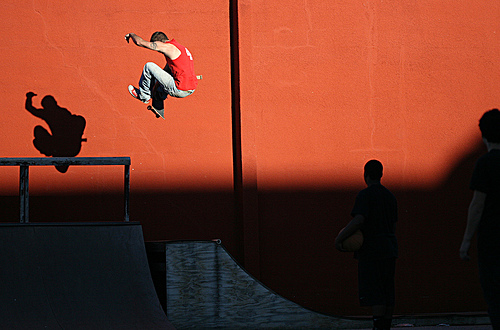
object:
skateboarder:
[126, 31, 201, 120]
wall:
[1, 8, 484, 184]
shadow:
[24, 92, 84, 174]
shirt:
[159, 40, 197, 91]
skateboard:
[149, 82, 166, 120]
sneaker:
[127, 84, 148, 102]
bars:
[0, 153, 131, 168]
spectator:
[335, 158, 401, 327]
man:
[459, 108, 497, 328]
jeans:
[478, 229, 500, 323]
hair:
[150, 31, 167, 41]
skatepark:
[1, 3, 499, 326]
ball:
[341, 228, 361, 248]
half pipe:
[228, 178, 251, 328]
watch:
[125, 33, 131, 39]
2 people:
[338, 158, 400, 327]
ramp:
[1, 225, 177, 329]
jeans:
[135, 63, 194, 103]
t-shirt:
[359, 186, 396, 256]